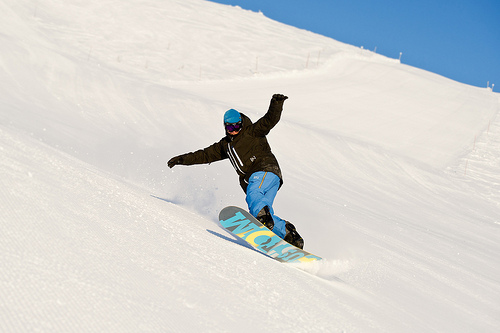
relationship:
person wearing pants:
[166, 93, 305, 250] [238, 164, 305, 260]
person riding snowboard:
[166, 93, 305, 250] [216, 206, 329, 273]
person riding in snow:
[166, 93, 305, 250] [3, 2, 172, 329]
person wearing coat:
[166, 93, 305, 250] [174, 102, 284, 195]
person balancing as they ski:
[154, 81, 334, 276] [207, 199, 322, 274]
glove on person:
[264, 90, 288, 108] [121, 84, 323, 241]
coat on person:
[174, 97, 283, 192] [167, 88, 305, 247]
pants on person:
[254, 175, 295, 222] [157, 90, 295, 240]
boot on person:
[285, 223, 310, 248] [167, 88, 305, 247]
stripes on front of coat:
[224, 138, 246, 178] [174, 97, 283, 192]